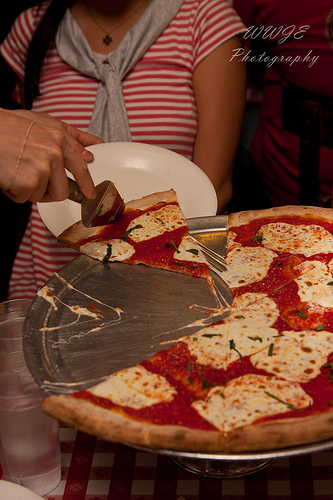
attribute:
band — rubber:
[6, 113, 50, 202]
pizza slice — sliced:
[63, 188, 212, 280]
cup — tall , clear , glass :
[0, 293, 80, 498]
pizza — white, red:
[53, 187, 212, 282]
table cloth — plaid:
[6, 417, 329, 499]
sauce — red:
[138, 241, 163, 259]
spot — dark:
[169, 422, 198, 450]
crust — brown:
[40, 393, 151, 445]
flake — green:
[195, 372, 213, 389]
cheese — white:
[231, 250, 264, 276]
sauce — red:
[144, 243, 169, 260]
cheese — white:
[258, 221, 332, 256]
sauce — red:
[228, 214, 332, 247]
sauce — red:
[147, 341, 235, 416]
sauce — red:
[77, 200, 332, 436]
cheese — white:
[80, 204, 332, 431]